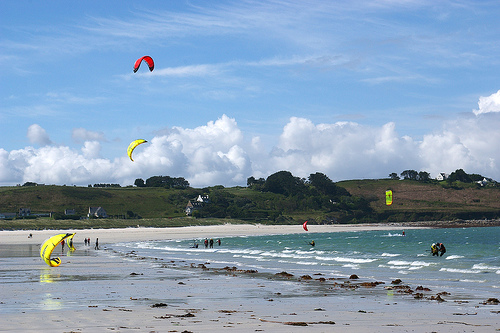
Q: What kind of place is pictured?
A: It is a beach.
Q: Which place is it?
A: It is a beach.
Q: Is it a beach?
A: Yes, it is a beach.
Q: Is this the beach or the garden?
A: It is the beach.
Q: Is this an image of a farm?
A: No, the picture is showing a beach.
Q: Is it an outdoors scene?
A: Yes, it is outdoors.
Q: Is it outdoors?
A: Yes, it is outdoors.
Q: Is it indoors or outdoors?
A: It is outdoors.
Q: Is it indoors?
A: No, it is outdoors.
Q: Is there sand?
A: Yes, there is sand.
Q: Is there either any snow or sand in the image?
A: Yes, there is sand.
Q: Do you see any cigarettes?
A: No, there are no cigarettes.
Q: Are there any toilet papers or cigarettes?
A: No, there are no cigarettes or toilet papers.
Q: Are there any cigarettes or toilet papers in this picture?
A: No, there are no cigarettes or toilet papers.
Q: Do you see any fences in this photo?
A: No, there are no fences.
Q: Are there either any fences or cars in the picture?
A: No, there are no fences or cars.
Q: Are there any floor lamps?
A: No, there are no floor lamps.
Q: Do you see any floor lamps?
A: No, there are no floor lamps.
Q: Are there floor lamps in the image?
A: No, there are no floor lamps.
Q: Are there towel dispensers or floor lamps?
A: No, there are no floor lamps or towel dispensers.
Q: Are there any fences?
A: No, there are no fences.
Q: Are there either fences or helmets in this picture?
A: No, there are no fences or helmets.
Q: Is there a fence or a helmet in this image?
A: No, there are no fences or helmets.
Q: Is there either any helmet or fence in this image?
A: No, there are no fences or helmets.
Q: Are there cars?
A: No, there are no cars.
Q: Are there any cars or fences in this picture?
A: No, there are no cars or fences.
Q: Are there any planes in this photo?
A: No, there are no planes.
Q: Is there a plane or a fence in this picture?
A: No, there are no airplanes or fences.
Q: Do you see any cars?
A: No, there are no cars.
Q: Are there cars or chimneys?
A: No, there are no cars or chimneys.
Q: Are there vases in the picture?
A: No, there are no vases.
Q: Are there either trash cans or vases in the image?
A: No, there are no vases or trash cans.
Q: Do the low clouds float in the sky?
A: Yes, the clouds float in the sky.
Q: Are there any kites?
A: Yes, there is a kite.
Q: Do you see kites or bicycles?
A: Yes, there is a kite.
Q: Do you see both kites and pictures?
A: No, there is a kite but no pictures.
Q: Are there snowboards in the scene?
A: No, there are no snowboards.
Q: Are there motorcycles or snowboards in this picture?
A: No, there are no snowboards or motorcycles.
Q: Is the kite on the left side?
A: Yes, the kite is on the left of the image.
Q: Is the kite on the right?
A: No, the kite is on the left of the image.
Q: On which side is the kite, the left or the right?
A: The kite is on the left of the image.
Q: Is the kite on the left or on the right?
A: The kite is on the left of the image.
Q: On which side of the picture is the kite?
A: The kite is on the left of the image.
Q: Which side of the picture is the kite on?
A: The kite is on the left of the image.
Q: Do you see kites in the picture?
A: Yes, there is a kite.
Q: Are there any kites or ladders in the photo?
A: Yes, there is a kite.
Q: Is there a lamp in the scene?
A: No, there are no lamps.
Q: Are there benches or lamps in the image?
A: No, there are no lamps or benches.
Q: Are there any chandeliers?
A: No, there are no chandeliers.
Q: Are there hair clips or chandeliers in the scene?
A: No, there are no chandeliers or hair clips.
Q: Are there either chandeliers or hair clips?
A: No, there are no chandeliers or hair clips.